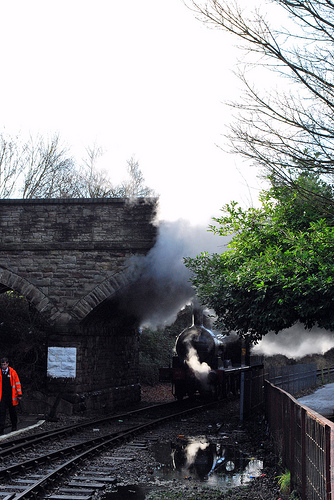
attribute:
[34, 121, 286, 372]
scene — happening, train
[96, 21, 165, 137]
sky — white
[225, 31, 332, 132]
tree — hanging, green, small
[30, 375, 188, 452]
track — curving, reflected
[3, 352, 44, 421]
jacket — orange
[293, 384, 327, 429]
water — large, puddle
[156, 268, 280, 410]
train — going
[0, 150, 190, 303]
bridge — stone, white, brick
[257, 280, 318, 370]
steam — white, old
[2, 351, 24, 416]
man — walking, standing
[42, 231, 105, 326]
wall — tall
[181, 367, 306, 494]
fence — iron, metal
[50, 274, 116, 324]
brick — white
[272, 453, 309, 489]
grass — green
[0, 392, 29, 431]
pant — black